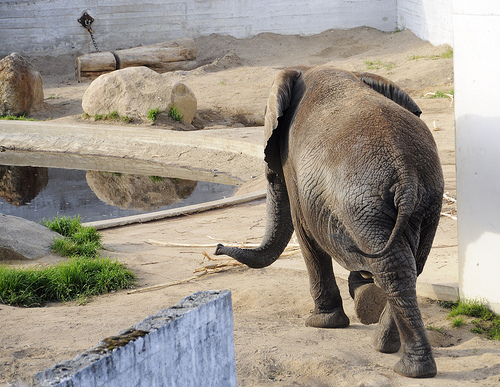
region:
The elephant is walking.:
[205, 44, 450, 381]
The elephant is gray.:
[187, 52, 459, 378]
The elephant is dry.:
[199, 50, 455, 381]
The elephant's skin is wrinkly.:
[176, 45, 450, 381]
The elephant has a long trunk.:
[193, 54, 444, 382]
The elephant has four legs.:
[193, 52, 453, 379]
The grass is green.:
[2, 210, 139, 313]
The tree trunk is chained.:
[63, 11, 208, 91]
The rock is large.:
[70, 60, 210, 137]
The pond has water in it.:
[0, 106, 291, 267]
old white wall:
[140, 286, 245, 379]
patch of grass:
[1, 255, 142, 305]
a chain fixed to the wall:
[70, 5, 110, 52]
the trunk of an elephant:
[210, 215, 290, 267]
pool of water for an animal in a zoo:
[0, 105, 260, 230]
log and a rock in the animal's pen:
[72, 40, 217, 120]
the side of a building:
[441, 0, 496, 305]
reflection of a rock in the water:
[82, 162, 202, 207]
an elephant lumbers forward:
[211, 36, 432, 381]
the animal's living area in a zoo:
[12, 13, 395, 310]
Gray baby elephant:
[267, 66, 458, 359]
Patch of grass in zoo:
[7, 245, 156, 317]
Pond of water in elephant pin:
[12, 144, 175, 209]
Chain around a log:
[86, 35, 122, 69]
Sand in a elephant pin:
[197, 40, 305, 82]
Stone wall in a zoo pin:
[73, 281, 289, 379]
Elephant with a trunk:
[213, 227, 278, 272]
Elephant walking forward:
[249, 135, 445, 363]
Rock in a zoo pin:
[86, 58, 207, 132]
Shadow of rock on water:
[66, 150, 188, 207]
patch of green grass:
[93, 258, 128, 290]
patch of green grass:
[62, 239, 102, 251]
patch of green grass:
[76, 227, 98, 238]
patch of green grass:
[53, 215, 86, 234]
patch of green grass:
[167, 108, 187, 126]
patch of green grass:
[146, 103, 163, 121]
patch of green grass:
[100, 105, 117, 126]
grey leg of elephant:
[374, 344, 440, 384]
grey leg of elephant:
[296, 297, 351, 330]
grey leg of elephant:
[349, 277, 380, 324]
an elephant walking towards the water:
[202, 57, 444, 372]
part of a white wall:
[31, 289, 238, 385]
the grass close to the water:
[2, 254, 140, 301]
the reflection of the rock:
[79, 159, 194, 210]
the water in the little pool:
[3, 151, 243, 223]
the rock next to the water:
[81, 62, 203, 131]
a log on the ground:
[77, 37, 196, 72]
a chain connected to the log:
[81, 16, 126, 71]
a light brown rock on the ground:
[0, 52, 53, 115]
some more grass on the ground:
[48, 215, 89, 254]